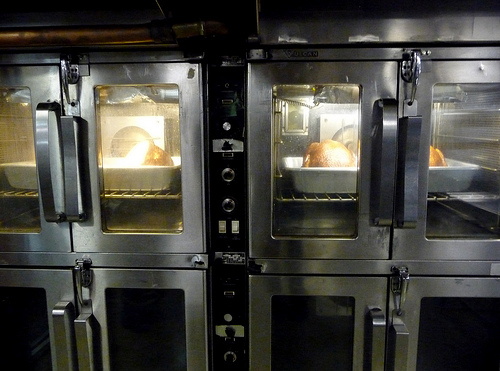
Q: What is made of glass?
A: The window.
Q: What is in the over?
A: Chicken.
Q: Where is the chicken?
A: In the oven.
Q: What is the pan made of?
A: Metal.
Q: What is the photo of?
A: Commercial oven.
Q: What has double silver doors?
A: The large commercial ovens.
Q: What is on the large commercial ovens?
A: Doors.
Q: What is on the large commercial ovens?
A: Silver doors.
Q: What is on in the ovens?
A: The light.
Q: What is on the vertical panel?
A: Switches.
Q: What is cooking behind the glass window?
A: Food.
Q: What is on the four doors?
A: Six silver handles.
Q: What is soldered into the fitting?
A: Copper pipe.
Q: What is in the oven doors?
A: Four observation windows.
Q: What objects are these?
A: Ovens.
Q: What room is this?
A: Kitchen.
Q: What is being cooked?
A: Food.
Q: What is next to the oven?
A: Another oven.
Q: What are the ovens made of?
A: Steel.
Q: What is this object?
A: Oven.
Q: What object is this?
A: Oven.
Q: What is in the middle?
A: Oven.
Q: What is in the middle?
A: Oven.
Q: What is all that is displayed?
A: Oven.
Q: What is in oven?
A: Bread.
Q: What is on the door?
A: Window.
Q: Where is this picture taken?
A: A kitchen.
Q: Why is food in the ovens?
A: To bake.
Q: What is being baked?
A: Chicken.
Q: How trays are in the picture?
A: Two.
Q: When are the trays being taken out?
A: When the food is done.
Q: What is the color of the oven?
A: Grey.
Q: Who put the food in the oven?
A: The cook.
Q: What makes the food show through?
A: Glass doors.